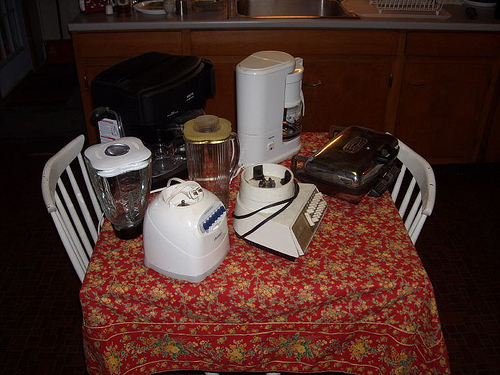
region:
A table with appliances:
[84, 41, 401, 356]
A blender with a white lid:
[84, 133, 155, 243]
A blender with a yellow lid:
[176, 111, 241, 188]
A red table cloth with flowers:
[99, 285, 427, 353]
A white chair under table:
[39, 131, 107, 282]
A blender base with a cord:
[231, 166, 332, 260]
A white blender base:
[136, 180, 236, 293]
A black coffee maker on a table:
[85, 56, 213, 173]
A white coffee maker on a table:
[223, 51, 307, 161]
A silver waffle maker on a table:
[296, 119, 413, 209]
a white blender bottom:
[144, 182, 231, 280]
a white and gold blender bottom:
[239, 165, 339, 261]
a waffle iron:
[300, 128, 397, 205]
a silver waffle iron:
[308, 131, 396, 198]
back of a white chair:
[40, 131, 90, 275]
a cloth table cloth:
[90, 266, 428, 366]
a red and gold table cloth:
[86, 277, 444, 373]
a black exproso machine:
[93, 53, 209, 203]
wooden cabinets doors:
[338, 37, 484, 132]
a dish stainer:
[355, 1, 437, 21]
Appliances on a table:
[77, 50, 429, 330]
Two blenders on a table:
[84, 115, 327, 282]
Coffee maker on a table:
[232, 45, 302, 156]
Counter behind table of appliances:
[68, 5, 495, 22]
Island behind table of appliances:
[65, 2, 497, 168]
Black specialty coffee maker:
[89, 50, 210, 182]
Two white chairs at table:
[44, 133, 430, 275]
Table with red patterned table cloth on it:
[83, 132, 450, 374]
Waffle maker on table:
[302, 117, 400, 194]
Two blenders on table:
[78, 114, 325, 278]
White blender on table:
[133, 172, 236, 284]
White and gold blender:
[224, 151, 335, 268]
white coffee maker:
[226, 46, 314, 170]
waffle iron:
[290, 122, 409, 206]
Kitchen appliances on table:
[80, 45, 410, 285]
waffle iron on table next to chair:
[293, 98, 440, 251]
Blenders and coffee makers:
[90, 41, 327, 276]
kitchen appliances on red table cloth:
[24, 107, 442, 317]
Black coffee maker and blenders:
[86, 40, 221, 186]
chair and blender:
[29, 130, 158, 237]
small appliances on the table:
[99, 45, 381, 243]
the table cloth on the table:
[88, 237, 433, 366]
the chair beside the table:
[383, 125, 450, 244]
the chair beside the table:
[23, 142, 98, 250]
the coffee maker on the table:
[222, 43, 313, 160]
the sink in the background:
[224, 3, 361, 27]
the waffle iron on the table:
[295, 126, 418, 211]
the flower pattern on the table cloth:
[259, 328, 319, 365]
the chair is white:
[25, 133, 90, 277]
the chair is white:
[383, 135, 460, 252]